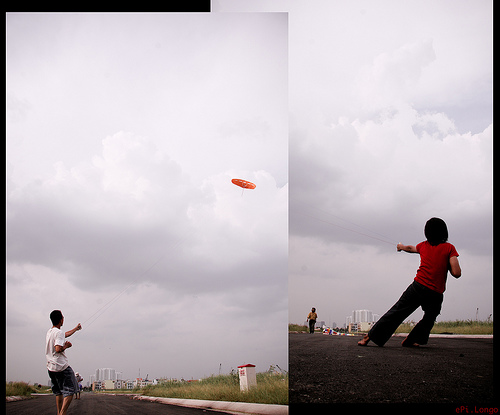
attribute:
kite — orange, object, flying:
[227, 176, 257, 194]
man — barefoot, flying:
[44, 309, 84, 414]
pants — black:
[361, 273, 442, 346]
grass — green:
[138, 375, 283, 405]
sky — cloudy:
[9, 3, 494, 312]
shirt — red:
[414, 241, 457, 292]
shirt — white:
[46, 327, 70, 374]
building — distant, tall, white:
[95, 361, 118, 386]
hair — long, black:
[424, 217, 447, 245]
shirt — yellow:
[309, 310, 318, 320]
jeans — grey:
[49, 369, 80, 396]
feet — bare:
[351, 331, 371, 350]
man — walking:
[308, 305, 320, 332]